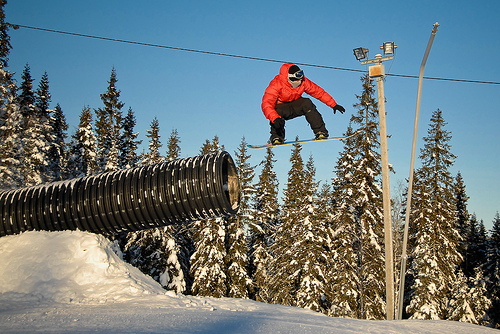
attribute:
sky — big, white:
[14, 10, 499, 63]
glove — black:
[329, 101, 345, 113]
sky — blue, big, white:
[0, 2, 498, 234]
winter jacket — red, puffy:
[258, 60, 336, 121]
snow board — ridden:
[243, 127, 371, 149]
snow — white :
[15, 225, 136, 307]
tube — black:
[2, 152, 238, 237]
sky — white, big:
[166, 8, 402, 42]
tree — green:
[417, 110, 462, 330]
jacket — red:
[263, 61, 350, 128]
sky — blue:
[135, 54, 256, 113]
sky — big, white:
[435, 21, 468, 86]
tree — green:
[402, 113, 485, 331]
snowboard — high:
[241, 124, 368, 162]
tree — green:
[294, 152, 337, 302]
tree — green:
[3, 73, 70, 195]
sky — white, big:
[129, 21, 460, 48]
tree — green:
[77, 70, 184, 170]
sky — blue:
[160, 5, 225, 37]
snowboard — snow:
[246, 130, 361, 150]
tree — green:
[188, 136, 255, 298]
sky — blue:
[39, 6, 496, 76]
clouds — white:
[3, 1, 498, 235]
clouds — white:
[59, 18, 231, 127]